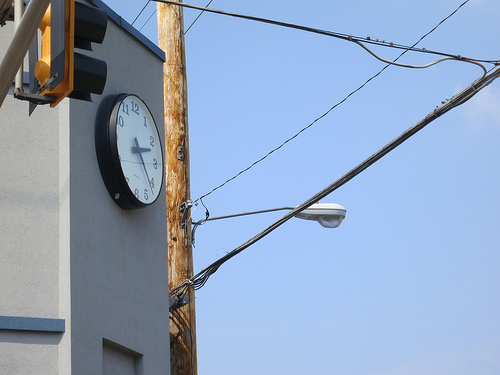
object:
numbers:
[131, 101, 141, 115]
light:
[295, 202, 345, 227]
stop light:
[12, 1, 111, 112]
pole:
[0, 0, 53, 116]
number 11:
[120, 102, 130, 115]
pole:
[5, 10, 35, 76]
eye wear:
[355, 186, 486, 336]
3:
[151, 157, 160, 171]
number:
[147, 132, 156, 149]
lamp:
[199, 202, 349, 230]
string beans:
[91, 87, 171, 214]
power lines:
[183, 2, 495, 259]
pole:
[158, 3, 192, 373]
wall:
[83, 237, 149, 299]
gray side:
[6, 110, 50, 317]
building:
[0, 1, 191, 374]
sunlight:
[6, 1, 172, 373]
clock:
[93, 84, 169, 213]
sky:
[103, 2, 497, 373]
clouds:
[372, 208, 477, 313]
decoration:
[73, 247, 137, 340]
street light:
[216, 185, 361, 258]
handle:
[127, 134, 156, 183]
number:
[134, 187, 140, 200]